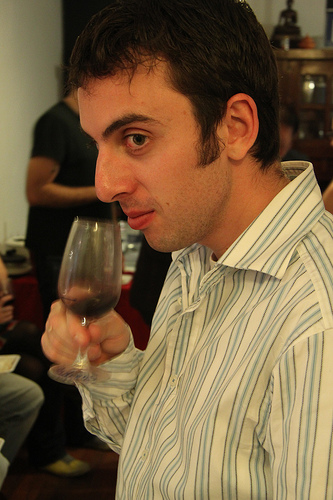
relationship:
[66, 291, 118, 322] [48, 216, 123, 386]
dark liquid in a wine glass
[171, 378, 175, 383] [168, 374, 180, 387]
blue string in middle of a white button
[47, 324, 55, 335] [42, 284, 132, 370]
gold ring on a right hand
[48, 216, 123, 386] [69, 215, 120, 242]
wine glass that blurry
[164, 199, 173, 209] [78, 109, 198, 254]
mole on man's face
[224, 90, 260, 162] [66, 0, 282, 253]
ear on man's head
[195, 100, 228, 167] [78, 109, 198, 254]
sideburn on man's face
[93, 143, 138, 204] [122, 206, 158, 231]
nose above h lips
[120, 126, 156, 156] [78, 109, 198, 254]
left eye on man's face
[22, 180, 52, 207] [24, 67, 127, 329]
elbow of woman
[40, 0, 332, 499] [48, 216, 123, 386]
man holding wine glass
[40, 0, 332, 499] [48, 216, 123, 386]
man swirling a wine glass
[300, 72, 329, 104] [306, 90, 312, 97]
shakers that are stainless steel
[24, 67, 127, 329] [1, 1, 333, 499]
woman in background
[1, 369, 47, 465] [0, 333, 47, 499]
grey pants on man in background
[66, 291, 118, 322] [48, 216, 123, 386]
dark liquid in wine glass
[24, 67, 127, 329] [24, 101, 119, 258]
woman wearing a black shirt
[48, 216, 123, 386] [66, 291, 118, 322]
wine glass that for a dark liquid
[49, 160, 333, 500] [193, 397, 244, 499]
shirt that striped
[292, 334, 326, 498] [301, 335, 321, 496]
stripes that are blue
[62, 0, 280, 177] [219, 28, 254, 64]
hair that brown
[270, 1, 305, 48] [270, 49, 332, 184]
buddha on mantle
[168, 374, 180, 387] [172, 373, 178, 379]
white button that white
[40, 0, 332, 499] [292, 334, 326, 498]
man wearing stripes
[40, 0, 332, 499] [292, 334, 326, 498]
man has on stripes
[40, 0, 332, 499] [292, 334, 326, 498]
man has on a shirt with stripes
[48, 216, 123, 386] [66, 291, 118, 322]
wine glass with a little dark liquid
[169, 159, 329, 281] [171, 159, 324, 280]
shirt collar worn down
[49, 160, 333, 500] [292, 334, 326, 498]
shirt with stripes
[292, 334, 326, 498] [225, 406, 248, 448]
stripes that are black,blue & white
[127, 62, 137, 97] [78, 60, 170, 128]
strand of hair on h forehead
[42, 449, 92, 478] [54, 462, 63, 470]
shoe that bright yellow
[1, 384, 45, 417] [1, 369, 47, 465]
long wrinkles on grey pants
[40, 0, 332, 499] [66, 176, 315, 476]
man wears shirt